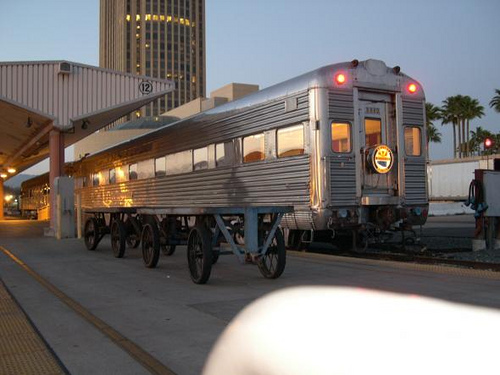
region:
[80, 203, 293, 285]
a metal cart parked next to the train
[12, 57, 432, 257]
a silver train parked at the station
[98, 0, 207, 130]
a tall building behind the train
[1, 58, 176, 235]
a covered waiting area next to the train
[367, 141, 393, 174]
round, lit object on the back of the train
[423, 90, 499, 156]
palm trees behind the train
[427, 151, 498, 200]
white wall behind the train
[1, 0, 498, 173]
dark sky above the train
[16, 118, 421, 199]
windows on the train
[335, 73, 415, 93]
red taillights on the train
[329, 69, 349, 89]
bright red light on back of train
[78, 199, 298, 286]
black wheeled metal carts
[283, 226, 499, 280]
tracks for train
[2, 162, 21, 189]
lights at train station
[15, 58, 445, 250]
silver stopped train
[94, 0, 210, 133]
tall building in background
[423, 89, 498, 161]
palm trees in the background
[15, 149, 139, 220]
reflection of sun on train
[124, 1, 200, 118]
reflection of sun on building windows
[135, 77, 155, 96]
number twelve sign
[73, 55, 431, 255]
a silver train passenger car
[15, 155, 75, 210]
a silver train passenger car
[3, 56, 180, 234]
a train station overhead shelter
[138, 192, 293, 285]
a light blue wagon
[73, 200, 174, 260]
a light blue wagon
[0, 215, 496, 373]
a train station boarding platform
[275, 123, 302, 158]
a train passenger window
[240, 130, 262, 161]
a train passenger window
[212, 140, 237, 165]
a train passenger window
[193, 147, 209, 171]
a train passenger window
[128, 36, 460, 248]
a passenger train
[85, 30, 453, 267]
a silver train car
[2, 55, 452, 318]
a passenger train at a stop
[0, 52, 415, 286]
a train at a platform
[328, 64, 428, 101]
red lights on a train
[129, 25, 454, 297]
an empty train car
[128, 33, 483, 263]
an empty silver train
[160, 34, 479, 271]
a train car stopped on the tracks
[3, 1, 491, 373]
a train station with no people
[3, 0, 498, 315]
an empty train station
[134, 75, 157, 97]
the number 12 in a circle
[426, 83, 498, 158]
several palm trees in background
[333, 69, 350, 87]
red light on train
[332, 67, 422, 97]
two red lights on train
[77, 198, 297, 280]
luggage trolley next to train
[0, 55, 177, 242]
shelter for train passengers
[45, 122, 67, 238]
post for passenger shelter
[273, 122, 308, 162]
window in train's rear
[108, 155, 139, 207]
reflection of setting sun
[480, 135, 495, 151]
street light in background